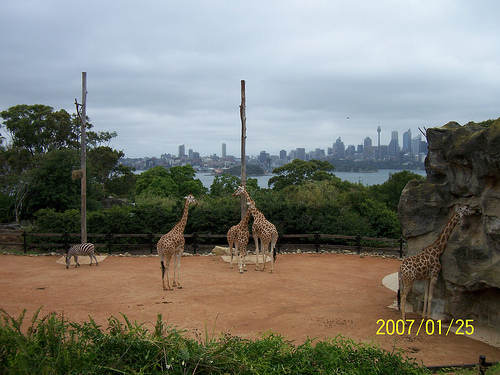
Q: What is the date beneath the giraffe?
A: 2007/01/25.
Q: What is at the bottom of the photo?
A: Green vegetation.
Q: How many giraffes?
A: 5.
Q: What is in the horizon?
A: A city.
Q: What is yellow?
A: Numbers.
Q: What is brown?
A: Ground.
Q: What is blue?
A: Sky.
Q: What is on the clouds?
A: Water.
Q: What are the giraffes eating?
A: Leaves.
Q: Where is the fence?
A: Behind the giraffes.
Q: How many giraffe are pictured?
A: Four.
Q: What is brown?
A: Dirt.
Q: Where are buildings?
A: In the distance.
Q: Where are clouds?
A: In the sky.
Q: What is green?
A: Trees.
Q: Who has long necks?
A: The giraffe.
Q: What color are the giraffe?
A: Brown and beige.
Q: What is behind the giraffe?
A: A fence.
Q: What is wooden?
A: The fence.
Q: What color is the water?
A: Blue.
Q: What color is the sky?
A: Blue.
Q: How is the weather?
A: Clear.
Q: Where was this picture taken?
A: A zoo.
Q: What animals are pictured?
A: Giraffes and a zebra.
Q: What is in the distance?
A: A cityscape.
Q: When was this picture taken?
A: Daytime.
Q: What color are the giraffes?
A: Brown and white.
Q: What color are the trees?
A: Green.